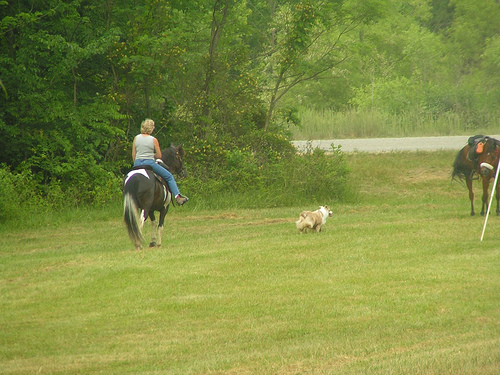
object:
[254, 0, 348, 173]
tree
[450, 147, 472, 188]
tail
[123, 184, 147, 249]
tail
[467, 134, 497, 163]
saddle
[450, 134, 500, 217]
horse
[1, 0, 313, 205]
leaves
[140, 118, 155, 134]
hair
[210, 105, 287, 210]
bushes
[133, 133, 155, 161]
shirt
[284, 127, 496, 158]
road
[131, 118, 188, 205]
person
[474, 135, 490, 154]
bed roll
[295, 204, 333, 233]
dog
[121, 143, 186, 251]
horse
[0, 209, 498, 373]
ground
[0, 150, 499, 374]
grass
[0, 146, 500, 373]
field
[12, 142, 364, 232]
vegatation